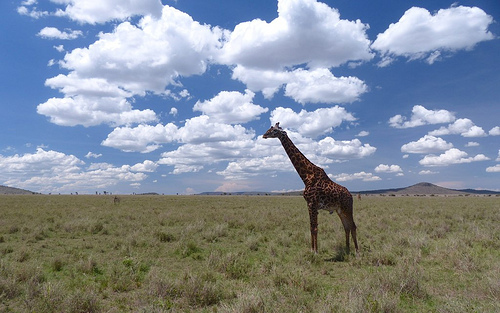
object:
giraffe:
[262, 121, 362, 261]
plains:
[103, 233, 149, 272]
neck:
[278, 134, 320, 178]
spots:
[298, 162, 307, 169]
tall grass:
[1, 193, 303, 313]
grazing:
[0, 0, 499, 311]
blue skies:
[1, 0, 498, 123]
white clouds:
[371, 4, 493, 54]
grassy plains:
[0, 193, 497, 313]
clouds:
[64, 7, 215, 83]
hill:
[382, 179, 465, 197]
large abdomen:
[303, 182, 357, 212]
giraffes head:
[261, 122, 283, 140]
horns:
[271, 120, 281, 129]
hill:
[0, 181, 45, 199]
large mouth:
[260, 132, 272, 140]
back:
[317, 165, 353, 202]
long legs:
[338, 204, 353, 257]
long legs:
[307, 204, 320, 257]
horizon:
[1, 177, 299, 210]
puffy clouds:
[220, 0, 373, 72]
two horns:
[272, 121, 282, 129]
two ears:
[272, 128, 279, 134]